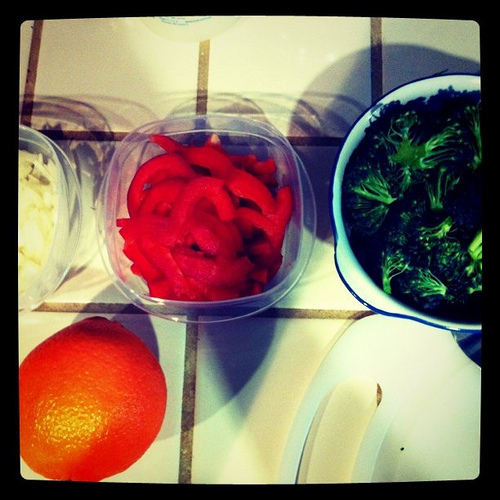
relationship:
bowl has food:
[218, 95, 310, 162] [95, 129, 272, 305]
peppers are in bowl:
[119, 133, 291, 295] [95, 115, 317, 324]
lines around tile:
[1, 41, 351, 489] [179, 41, 380, 149]